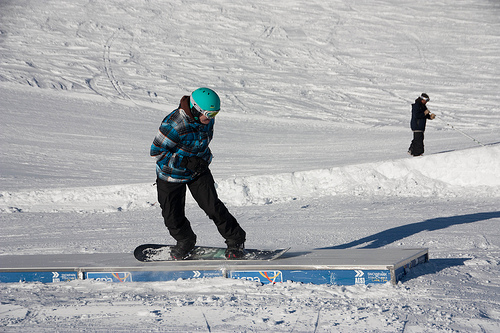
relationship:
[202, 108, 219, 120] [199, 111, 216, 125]
goggles are on face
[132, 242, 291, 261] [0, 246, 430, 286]
snowboard on ramp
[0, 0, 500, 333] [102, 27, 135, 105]
ground has track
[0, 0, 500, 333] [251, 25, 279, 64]
ground has track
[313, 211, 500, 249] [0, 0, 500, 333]
shadow on ground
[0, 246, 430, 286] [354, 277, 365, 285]
ramp has letters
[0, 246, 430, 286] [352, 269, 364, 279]
ramp has arrows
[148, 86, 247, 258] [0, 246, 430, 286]
person on ramp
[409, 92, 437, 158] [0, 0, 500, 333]
person standing on ground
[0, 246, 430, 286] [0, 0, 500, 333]
ramp on ground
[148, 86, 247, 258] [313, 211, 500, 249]
person has shadow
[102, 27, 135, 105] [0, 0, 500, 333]
track on ground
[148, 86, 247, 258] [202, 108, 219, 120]
person wears goggles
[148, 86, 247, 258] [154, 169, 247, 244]
person wears pants